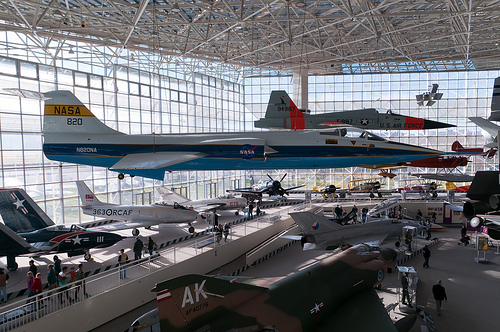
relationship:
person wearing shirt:
[24, 267, 44, 319] [22, 256, 42, 291]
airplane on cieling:
[39, 90, 484, 181] [9, 5, 483, 75]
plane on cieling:
[253, 89, 454, 129] [9, 5, 483, 75]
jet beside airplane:
[0, 187, 136, 270] [76, 180, 199, 229]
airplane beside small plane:
[76, 180, 199, 229] [156, 185, 248, 215]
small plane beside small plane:
[156, 185, 248, 215] [226, 174, 306, 198]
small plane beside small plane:
[226, 174, 306, 198] [294, 182, 354, 199]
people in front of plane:
[22, 256, 95, 299] [0, 187, 137, 269]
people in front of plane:
[118, 235, 161, 275] [131, 242, 402, 330]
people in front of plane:
[335, 203, 368, 218] [39, 87, 454, 182]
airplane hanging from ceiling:
[250, 87, 467, 132] [2, 1, 497, 72]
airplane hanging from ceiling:
[37, 86, 447, 183] [2, 1, 497, 72]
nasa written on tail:
[42, 94, 99, 121] [16, 78, 126, 161]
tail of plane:
[16, 78, 126, 161] [14, 70, 496, 197]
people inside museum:
[43, 264, 61, 300] [8, 24, 491, 325]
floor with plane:
[81, 202, 496, 330] [129, 238, 406, 326]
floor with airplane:
[81, 202, 496, 330] [280, 211, 428, 252]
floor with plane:
[81, 202, 496, 330] [442, 166, 499, 257]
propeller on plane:
[262, 174, 289, 198] [226, 170, 314, 203]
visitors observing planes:
[0, 236, 155, 315] [1, 85, 498, 330]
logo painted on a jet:
[59, 230, 94, 245] [0, 186, 129, 261]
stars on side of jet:
[66, 231, 81, 247] [0, 187, 136, 270]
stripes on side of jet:
[78, 234, 95, 244] [0, 187, 136, 270]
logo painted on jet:
[7, 190, 29, 217] [3, 178, 128, 273]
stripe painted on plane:
[43, 140, 437, 159] [0, 83, 482, 180]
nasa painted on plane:
[45, 105, 95, 116] [0, 83, 482, 180]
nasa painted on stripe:
[45, 105, 95, 116] [43, 140, 437, 159]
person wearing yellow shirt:
[107, 242, 137, 277] [115, 250, 131, 265]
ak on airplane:
[175, 277, 208, 310] [149, 242, 387, 332]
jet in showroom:
[0, 187, 136, 270] [0, 0, 500, 330]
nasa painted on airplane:
[234, 141, 258, 161] [39, 90, 484, 181]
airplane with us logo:
[254, 89, 457, 131] [361, 114, 371, 126]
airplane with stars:
[39, 90, 484, 181] [233, 143, 259, 156]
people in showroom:
[43, 264, 61, 300] [0, 0, 500, 330]